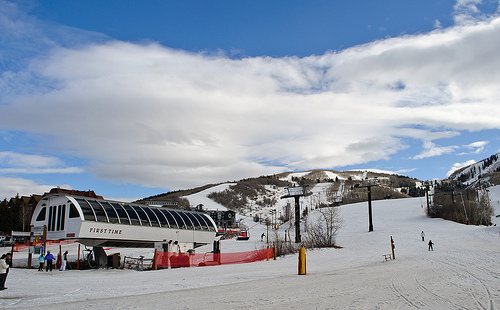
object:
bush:
[428, 180, 483, 222]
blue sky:
[174, 8, 343, 33]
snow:
[173, 276, 263, 295]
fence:
[151, 252, 289, 263]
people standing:
[58, 250, 68, 270]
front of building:
[24, 238, 131, 277]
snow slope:
[388, 189, 473, 299]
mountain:
[211, 169, 425, 213]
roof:
[68, 194, 217, 214]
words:
[89, 227, 122, 235]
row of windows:
[74, 197, 217, 232]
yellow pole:
[298, 245, 307, 275]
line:
[28, 244, 81, 269]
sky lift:
[16, 229, 163, 266]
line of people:
[44, 250, 56, 272]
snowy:
[376, 204, 424, 273]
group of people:
[420, 230, 434, 251]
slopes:
[351, 187, 420, 232]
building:
[30, 188, 219, 253]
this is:
[315, 146, 382, 184]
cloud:
[117, 65, 281, 143]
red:
[159, 254, 184, 266]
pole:
[153, 248, 158, 270]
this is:
[424, 183, 494, 227]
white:
[132, 229, 165, 238]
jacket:
[44, 254, 55, 260]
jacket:
[38, 255, 46, 263]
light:
[354, 183, 360, 188]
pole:
[366, 183, 373, 232]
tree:
[429, 184, 494, 227]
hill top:
[387, 193, 405, 227]